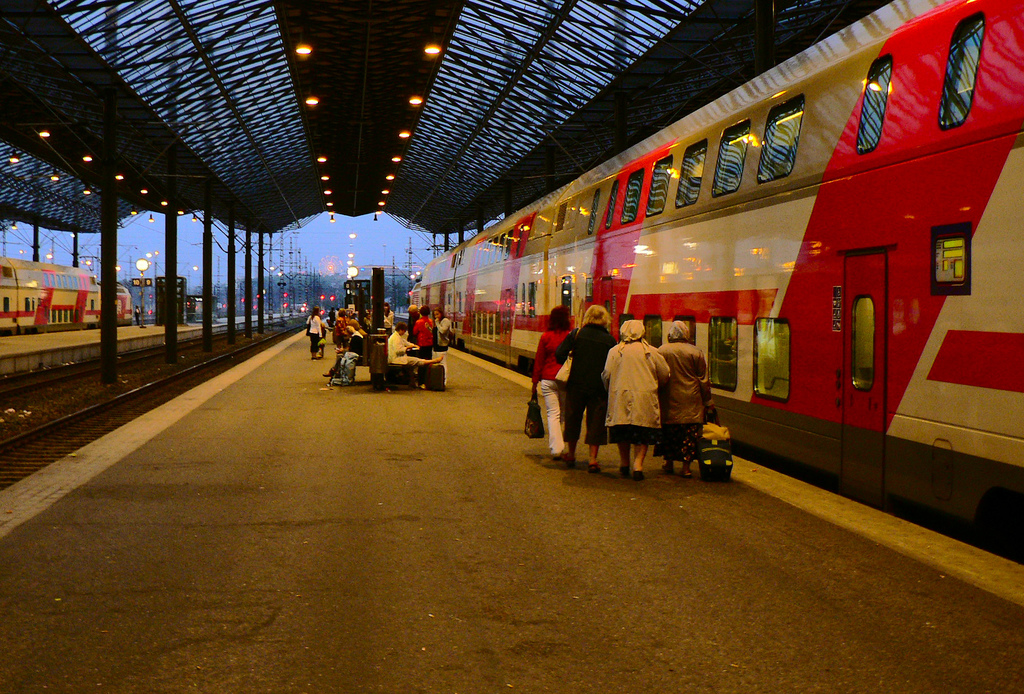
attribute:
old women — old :
[490, 284, 769, 490]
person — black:
[295, 303, 341, 377]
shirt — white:
[303, 310, 332, 337]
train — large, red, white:
[411, 7, 1016, 552]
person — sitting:
[382, 320, 449, 372]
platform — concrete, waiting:
[26, 316, 1012, 684]